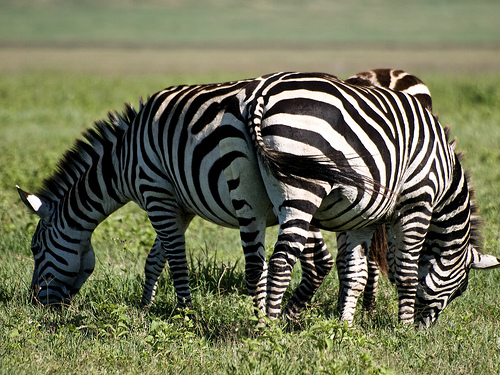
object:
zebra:
[14, 78, 280, 312]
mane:
[34, 95, 146, 194]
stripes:
[469, 245, 481, 264]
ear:
[471, 248, 500, 270]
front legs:
[394, 207, 434, 325]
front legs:
[363, 253, 379, 313]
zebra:
[341, 68, 433, 285]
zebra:
[219, 71, 500, 333]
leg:
[138, 183, 191, 309]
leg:
[141, 212, 194, 306]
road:
[3, 36, 498, 78]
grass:
[3, 3, 497, 366]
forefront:
[0, 204, 497, 365]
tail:
[368, 223, 388, 277]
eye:
[31, 246, 40, 255]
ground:
[2, 2, 496, 372]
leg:
[264, 178, 330, 323]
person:
[250, 71, 493, 330]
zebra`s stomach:
[170, 177, 238, 230]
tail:
[245, 97, 400, 203]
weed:
[162, 294, 210, 349]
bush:
[454, 75, 484, 105]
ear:
[15, 184, 51, 219]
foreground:
[0, 71, 500, 375]